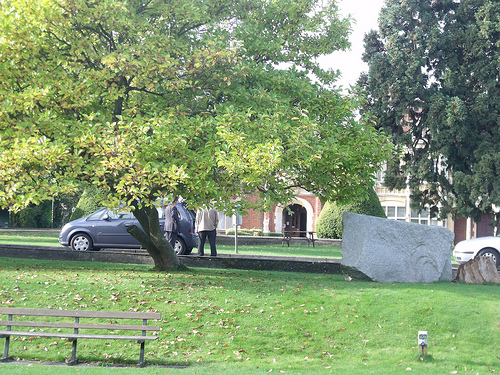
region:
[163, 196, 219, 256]
two men standing near a blue vehicle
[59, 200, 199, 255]
a parked blue minivan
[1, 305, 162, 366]
a wooden bench in a park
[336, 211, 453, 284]
a big gray stone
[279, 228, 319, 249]
a picnic table in front of the building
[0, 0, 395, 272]
a tree with green and yellow leaves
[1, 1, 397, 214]
yellow and green leaves on a tree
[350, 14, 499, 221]
green leaves on the tree branches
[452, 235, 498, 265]
the front of a parked white automobile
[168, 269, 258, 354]
leaves are on the ground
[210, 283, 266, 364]
the grass is covered with leaves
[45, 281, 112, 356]
the bench is brown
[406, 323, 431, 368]
a light is on the ground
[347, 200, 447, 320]
a large rock is on the ground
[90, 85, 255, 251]
the leaves are green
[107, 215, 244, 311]
the trunk is cut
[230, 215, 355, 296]
a wooden bench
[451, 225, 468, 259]
the car is white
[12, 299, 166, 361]
wooden bench in park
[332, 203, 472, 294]
large gray rock in park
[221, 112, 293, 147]
green leaves in brown tree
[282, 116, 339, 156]
green leaves in brown tree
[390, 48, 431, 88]
green leaves in brown tree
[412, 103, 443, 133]
green leaves in brown tree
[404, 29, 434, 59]
green leaves in brown tree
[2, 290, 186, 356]
the bench is empty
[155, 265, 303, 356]
leaves are on the grass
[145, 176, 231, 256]
two men standing together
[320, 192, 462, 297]
a big boulder on the grass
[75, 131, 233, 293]
the tree is leaning left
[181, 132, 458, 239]
a building in the background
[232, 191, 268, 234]
the building is made of bricks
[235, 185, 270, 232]
the bricks are reddish brown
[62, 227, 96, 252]
the tires are black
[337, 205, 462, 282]
LARGE ROCK IN FRONT OF BUILDING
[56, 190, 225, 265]
MEN STANDING BY A CAR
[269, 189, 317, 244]
DOORWAY TO A BUILDING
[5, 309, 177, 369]
BENCH IN THE GRASS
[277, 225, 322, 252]
PICNIC TABLE IN FRONT OF BUILDING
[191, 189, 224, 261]
MAN WEARING BLACK PANTS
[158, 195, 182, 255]
MAN WEARING ALL BLACK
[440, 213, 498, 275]
WHITE CAR NEXT TO ROCK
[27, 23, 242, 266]
LARGE TREE BY MEN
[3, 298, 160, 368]
The bench made of wood.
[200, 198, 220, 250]
A man with a tan coat.